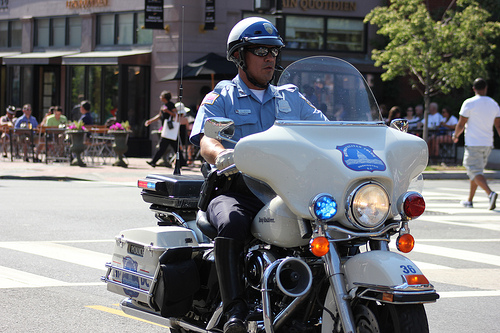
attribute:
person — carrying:
[150, 96, 197, 171]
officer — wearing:
[176, 3, 370, 325]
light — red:
[395, 189, 437, 227]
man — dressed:
[142, 89, 175, 169]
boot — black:
[211, 232, 251, 331]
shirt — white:
[456, 94, 493, 151]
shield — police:
[330, 134, 396, 181]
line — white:
[0, 227, 116, 276]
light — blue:
[302, 188, 342, 222]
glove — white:
[207, 138, 242, 189]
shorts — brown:
[459, 145, 496, 180]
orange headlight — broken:
[310, 234, 333, 257]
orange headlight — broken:
[396, 231, 419, 253]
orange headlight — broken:
[401, 271, 432, 284]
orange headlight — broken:
[399, 188, 426, 220]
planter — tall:
[101, 111, 137, 163]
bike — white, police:
[46, 160, 473, 331]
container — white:
[97, 220, 196, 324]